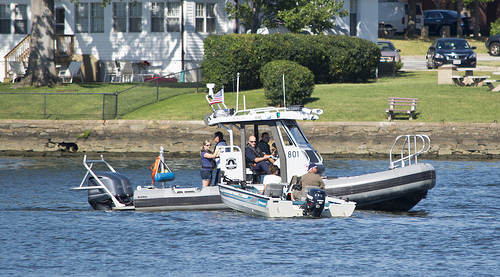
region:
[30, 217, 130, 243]
calm blue waters in the bay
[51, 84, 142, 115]
green chain link fence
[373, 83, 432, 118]
small pink bench on grass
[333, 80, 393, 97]
well cultivated green grass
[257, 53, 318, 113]
large round green tree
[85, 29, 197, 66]
white panels on white house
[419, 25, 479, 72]
blue passenger car in parking space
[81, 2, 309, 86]
large white house on shore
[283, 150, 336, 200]
man in white boat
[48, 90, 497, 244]
large boat filled with people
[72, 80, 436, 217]
Boat on the water by a smaller boat.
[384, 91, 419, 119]
Wood bench on the bank.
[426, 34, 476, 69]
Black car to the right of a house.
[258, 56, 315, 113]
Bush close to the water.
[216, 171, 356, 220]
Smaller boat in the water.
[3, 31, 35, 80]
Wooden rails on a staircase going to a house.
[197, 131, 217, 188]
A blonde haired woman standing in a purple shirt.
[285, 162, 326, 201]
A man sitting in a smaller boat.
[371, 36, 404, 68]
A barely visible car sitting directly to the right of a house.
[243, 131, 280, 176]
Two guys sitting in a larger boat.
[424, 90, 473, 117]
this is the grass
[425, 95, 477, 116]
the grass is green in color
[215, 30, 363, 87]
this is a hedge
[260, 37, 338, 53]
the leaves are green in color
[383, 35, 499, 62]
these are three cars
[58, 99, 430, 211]
these are two boats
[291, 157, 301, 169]
the boat is white in color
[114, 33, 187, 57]
this is the wall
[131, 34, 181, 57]
the wall is white in color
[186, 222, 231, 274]
this is the water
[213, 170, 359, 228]
white and blue fishing boat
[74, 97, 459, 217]
two engine police boat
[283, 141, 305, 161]
number 801 on police boat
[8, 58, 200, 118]
black fence around yard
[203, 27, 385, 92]
Green hedges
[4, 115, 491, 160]
brown stone sea wall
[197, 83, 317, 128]
united states flag on police boat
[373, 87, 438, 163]
brown park bench behind sea wall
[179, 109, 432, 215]
six people on boats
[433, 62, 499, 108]
picinic tables in grass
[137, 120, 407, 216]
this is a boat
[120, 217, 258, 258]
this is a water body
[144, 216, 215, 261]
the water is calm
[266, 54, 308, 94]
this is a tree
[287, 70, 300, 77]
the tree has green leaves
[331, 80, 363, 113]
this is a grass area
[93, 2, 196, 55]
this is a building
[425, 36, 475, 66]
this is a car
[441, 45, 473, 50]
the car is black in color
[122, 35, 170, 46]
the wall is white in color